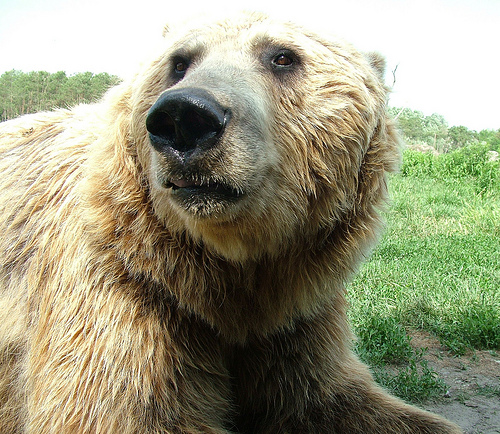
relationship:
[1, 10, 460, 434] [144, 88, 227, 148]
bear has nose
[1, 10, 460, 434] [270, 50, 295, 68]
bear has eye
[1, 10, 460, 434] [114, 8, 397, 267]
bear has head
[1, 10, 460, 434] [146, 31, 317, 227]
bear has face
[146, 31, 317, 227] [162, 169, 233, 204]
face has mouth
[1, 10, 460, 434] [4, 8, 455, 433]
bear has hair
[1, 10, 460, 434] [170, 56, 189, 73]
bear has eye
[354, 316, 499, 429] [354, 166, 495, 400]
dirt by grass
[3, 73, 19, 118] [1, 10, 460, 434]
tree behind bear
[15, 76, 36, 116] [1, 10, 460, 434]
tree behind bear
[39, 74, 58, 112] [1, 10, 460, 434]
tree behind bear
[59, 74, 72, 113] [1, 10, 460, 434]
tree behind bear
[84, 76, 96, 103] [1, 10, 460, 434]
tree behind bear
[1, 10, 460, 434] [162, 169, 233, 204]
bear has mouth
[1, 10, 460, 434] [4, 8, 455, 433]
bear covered with hair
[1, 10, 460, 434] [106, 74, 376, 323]
bear has neck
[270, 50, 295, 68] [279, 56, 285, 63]
eye has spot